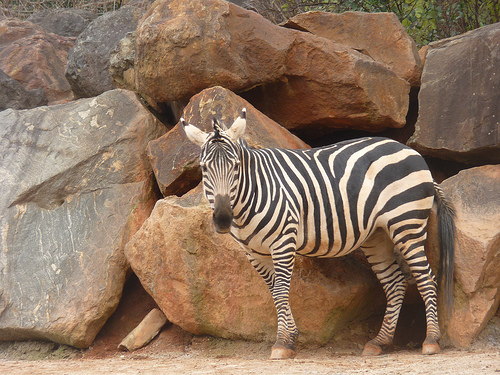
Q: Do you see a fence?
A: No, there are no fences.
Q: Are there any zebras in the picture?
A: Yes, there is a zebra.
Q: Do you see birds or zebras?
A: Yes, there is a zebra.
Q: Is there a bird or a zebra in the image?
A: Yes, there is a zebra.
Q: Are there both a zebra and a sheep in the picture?
A: No, there is a zebra but no sheep.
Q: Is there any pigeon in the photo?
A: No, there are no pigeons.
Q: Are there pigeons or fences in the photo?
A: No, there are no pigeons or fences.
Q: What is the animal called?
A: The animal is a zebra.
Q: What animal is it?
A: The animal is a zebra.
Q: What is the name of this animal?
A: That is a zebra.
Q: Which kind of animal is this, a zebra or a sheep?
A: That is a zebra.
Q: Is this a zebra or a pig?
A: This is a zebra.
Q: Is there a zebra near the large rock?
A: Yes, there is a zebra near the rock.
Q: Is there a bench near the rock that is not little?
A: No, there is a zebra near the rock.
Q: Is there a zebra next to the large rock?
A: Yes, there is a zebra next to the rock.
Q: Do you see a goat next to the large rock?
A: No, there is a zebra next to the rock.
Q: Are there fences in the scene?
A: No, there are no fences.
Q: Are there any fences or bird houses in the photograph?
A: No, there are no fences or bird houses.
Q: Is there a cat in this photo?
A: No, there are no cats.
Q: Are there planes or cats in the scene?
A: No, there are no cats or planes.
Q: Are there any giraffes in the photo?
A: No, there are no giraffes.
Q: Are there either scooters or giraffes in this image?
A: No, there are no giraffes or scooters.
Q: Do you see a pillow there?
A: No, there are no pillows.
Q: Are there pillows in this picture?
A: No, there are no pillows.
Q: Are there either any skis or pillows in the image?
A: No, there are no pillows or skis.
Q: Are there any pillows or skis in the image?
A: No, there are no pillows or skis.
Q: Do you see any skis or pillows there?
A: No, there are no pillows or skis.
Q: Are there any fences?
A: No, there are no fences.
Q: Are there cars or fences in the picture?
A: No, there are no fences or cars.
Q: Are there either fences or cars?
A: No, there are no fences or cars.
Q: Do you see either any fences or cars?
A: No, there are no fences or cars.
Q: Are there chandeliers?
A: No, there are no chandeliers.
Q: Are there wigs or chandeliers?
A: No, there are no chandeliers or wigs.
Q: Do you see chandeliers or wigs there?
A: No, there are no chandeliers or wigs.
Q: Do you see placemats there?
A: No, there are no placemats.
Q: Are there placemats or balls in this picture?
A: No, there are no placemats or balls.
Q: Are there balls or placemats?
A: No, there are no placemats or balls.